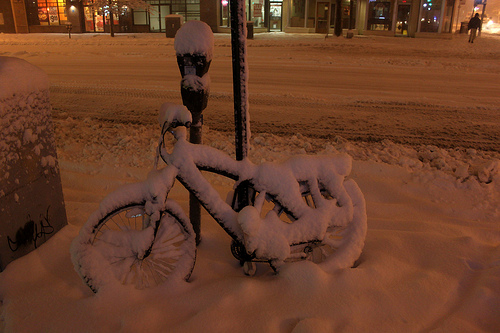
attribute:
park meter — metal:
[164, 20, 222, 138]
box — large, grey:
[2, 78, 68, 252]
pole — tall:
[338, 15, 346, 32]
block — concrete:
[0, 54, 70, 272]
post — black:
[215, 0, 257, 192]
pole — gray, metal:
[183, 100, 209, 254]